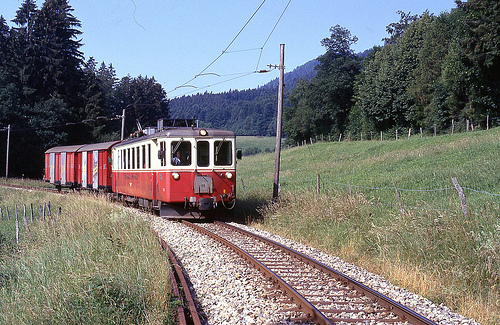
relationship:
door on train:
[138, 135, 190, 199] [36, 120, 242, 221]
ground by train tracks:
[429, 160, 484, 215] [8, 168, 454, 323]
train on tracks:
[50, 110, 250, 223] [6, 172, 435, 322]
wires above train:
[2, 0, 334, 142] [18, 103, 270, 220]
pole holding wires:
[269, 40, 289, 212] [118, 58, 288, 100]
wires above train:
[118, 58, 288, 100] [26, 81, 289, 246]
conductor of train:
[172, 147, 182, 162] [36, 120, 242, 221]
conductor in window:
[172, 147, 182, 162] [170, 141, 191, 167]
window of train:
[170, 141, 191, 167] [36, 120, 242, 221]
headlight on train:
[169, 171, 181, 183] [39, 124, 235, 219]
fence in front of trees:
[308, 121, 495, 149] [314, 53, 462, 134]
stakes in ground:
[11, 195, 65, 240] [1, 127, 499, 323]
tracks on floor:
[6, 172, 435, 322] [0, 128, 499, 323]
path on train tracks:
[167, 214, 467, 324] [178, 215, 426, 323]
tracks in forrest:
[6, 172, 435, 322] [1, 0, 499, 322]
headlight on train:
[169, 168, 234, 181] [36, 120, 242, 221]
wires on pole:
[165, 67, 272, 82] [272, 42, 285, 202]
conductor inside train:
[172, 151, 182, 165] [36, 120, 242, 221]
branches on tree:
[346, 9, 440, 139] [363, 15, 452, 130]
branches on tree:
[281, 22, 361, 148] [298, 22, 363, 143]